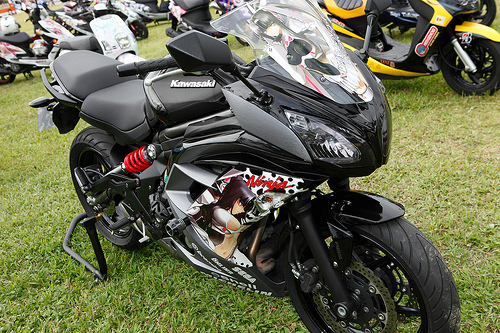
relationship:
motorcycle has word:
[29, 0, 462, 327] [245, 173, 295, 192]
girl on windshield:
[255, 12, 368, 105] [211, 1, 373, 106]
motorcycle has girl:
[29, 0, 462, 327] [255, 12, 368, 105]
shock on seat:
[108, 140, 157, 177] [55, 52, 160, 145]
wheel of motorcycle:
[283, 200, 462, 332] [29, 0, 462, 327]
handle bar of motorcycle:
[117, 44, 246, 76] [29, 0, 462, 327]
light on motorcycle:
[281, 109, 359, 165] [29, 0, 462, 327]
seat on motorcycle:
[55, 52, 160, 145] [29, 0, 462, 327]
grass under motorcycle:
[0, 18, 496, 329] [29, 0, 462, 327]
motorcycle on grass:
[29, 0, 462, 327] [0, 18, 496, 329]